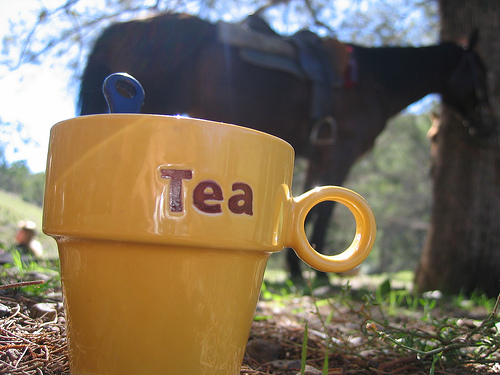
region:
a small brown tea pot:
[41, 114, 374, 374]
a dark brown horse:
[81, 11, 493, 286]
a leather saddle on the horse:
[217, 14, 357, 155]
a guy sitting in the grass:
[7, 226, 37, 256]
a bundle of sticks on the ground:
[1, 280, 66, 374]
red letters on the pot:
[159, 165, 254, 220]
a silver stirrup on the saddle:
[309, 114, 338, 145]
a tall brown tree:
[412, 0, 498, 305]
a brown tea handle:
[293, 186, 374, 273]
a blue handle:
[103, 72, 146, 113]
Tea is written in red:
[154, 167, 274, 228]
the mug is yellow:
[65, 105, 275, 365]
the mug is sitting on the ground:
[16, 317, 251, 373]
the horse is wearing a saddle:
[200, 6, 373, 124]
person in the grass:
[3, 216, 43, 278]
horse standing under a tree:
[117, 7, 490, 99]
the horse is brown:
[128, 28, 458, 123]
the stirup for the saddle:
[305, 92, 361, 156]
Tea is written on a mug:
[92, 156, 298, 257]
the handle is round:
[279, 186, 373, 264]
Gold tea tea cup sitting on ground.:
[32, 60, 377, 372]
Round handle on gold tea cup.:
[286, 180, 386, 280]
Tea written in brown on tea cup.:
[156, 164, 261, 224]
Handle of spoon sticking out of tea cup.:
[97, 68, 155, 133]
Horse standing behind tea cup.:
[79, 14, 498, 296]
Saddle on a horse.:
[235, 8, 366, 155]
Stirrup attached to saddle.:
[305, 116, 347, 150]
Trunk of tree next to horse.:
[418, 8, 496, 332]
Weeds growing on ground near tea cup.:
[301, 283, 498, 369]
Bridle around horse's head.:
[439, 38, 496, 117]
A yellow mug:
[35, 103, 418, 341]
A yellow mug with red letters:
[31, 95, 381, 353]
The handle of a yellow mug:
[138, 101, 384, 318]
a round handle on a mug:
[249, 150, 386, 317]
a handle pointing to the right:
[229, 149, 447, 287]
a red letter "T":
[146, 154, 194, 232]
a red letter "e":
[193, 166, 225, 226]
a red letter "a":
[224, 166, 262, 226]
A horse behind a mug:
[38, 25, 381, 254]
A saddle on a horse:
[199, 8, 366, 126]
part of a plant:
[367, 321, 392, 370]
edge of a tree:
[411, 224, 434, 261]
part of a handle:
[336, 196, 377, 266]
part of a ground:
[288, 314, 348, 367]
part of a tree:
[368, 134, 403, 188]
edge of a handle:
[295, 238, 342, 268]